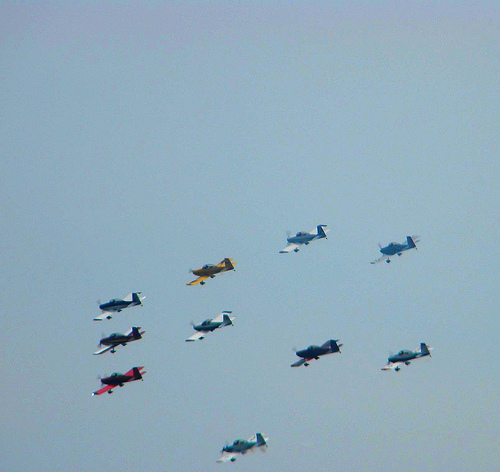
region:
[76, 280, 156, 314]
PLane in the sky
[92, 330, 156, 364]
PLane in the sky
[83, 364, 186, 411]
PLane in the sky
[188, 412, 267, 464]
PLane in the sky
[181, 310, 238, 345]
PLane in the sky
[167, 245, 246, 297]
PLane in the sky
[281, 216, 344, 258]
PLane in the sky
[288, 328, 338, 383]
PLane in the sky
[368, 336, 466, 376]
PLane in the sky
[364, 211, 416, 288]
PLane in the sky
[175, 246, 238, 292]
A yellow plane in sky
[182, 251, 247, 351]
Two planes flying in sky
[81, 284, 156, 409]
Three planes flying in sky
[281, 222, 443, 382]
Four planes flying in sky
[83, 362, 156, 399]
A red air plane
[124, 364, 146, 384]
Tail end of plane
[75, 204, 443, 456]
A large group of planes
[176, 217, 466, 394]
Six planes in sky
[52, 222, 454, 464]
A group of small planes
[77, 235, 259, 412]
five planes flying in sky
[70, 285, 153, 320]
plane doing tricks in air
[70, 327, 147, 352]
plane doing tricks in air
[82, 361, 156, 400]
plane doing tricks in air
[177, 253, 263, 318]
plane doing tricks in air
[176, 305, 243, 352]
plane doing tricks in air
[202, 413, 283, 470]
plane doing tricks in air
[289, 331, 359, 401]
plane doing tricks in air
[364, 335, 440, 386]
plane doing tricks in air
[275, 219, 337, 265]
plane doing tricks in air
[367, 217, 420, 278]
plane doing tricks in air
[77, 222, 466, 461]
Ten planes flying in the air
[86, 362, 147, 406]
Red plane in the lead formation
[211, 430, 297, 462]
Plane out of formation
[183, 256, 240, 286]
Yellow plane in second row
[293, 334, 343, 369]
Black plane is second from the back row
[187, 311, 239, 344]
Plane has white wings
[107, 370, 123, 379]
Window dome on the plane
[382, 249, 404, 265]
Wheels on the plane can be seen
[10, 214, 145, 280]
Sky is a murkey blue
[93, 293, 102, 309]
Propeller can be seen barely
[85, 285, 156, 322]
plane flying in formation in air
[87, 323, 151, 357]
plane flying in formation in air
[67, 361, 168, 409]
plane flying in formation in air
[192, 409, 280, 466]
plane flying in formation in air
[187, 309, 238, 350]
plane flying in formation in air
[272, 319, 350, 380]
plane flying in formation in air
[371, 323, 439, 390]
plane flying in formation in air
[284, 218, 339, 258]
plane flying in formation in air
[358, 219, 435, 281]
plane flying in formation in air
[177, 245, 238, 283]
plane flying in formation in air